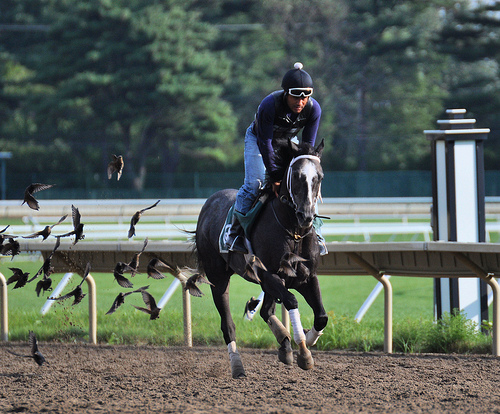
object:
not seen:
[6, 15, 500, 412]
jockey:
[197, 42, 354, 272]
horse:
[174, 157, 368, 387]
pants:
[227, 112, 279, 252]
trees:
[333, 46, 447, 175]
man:
[204, 55, 370, 322]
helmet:
[239, 55, 340, 121]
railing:
[1, 234, 498, 349]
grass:
[11, 282, 488, 357]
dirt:
[3, 334, 499, 411]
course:
[55, 277, 492, 392]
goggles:
[284, 86, 318, 99]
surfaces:
[79, 355, 210, 399]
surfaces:
[339, 314, 379, 344]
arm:
[255, 95, 282, 178]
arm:
[301, 101, 319, 154]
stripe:
[300, 159, 319, 206]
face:
[291, 159, 321, 228]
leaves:
[0, 0, 64, 33]